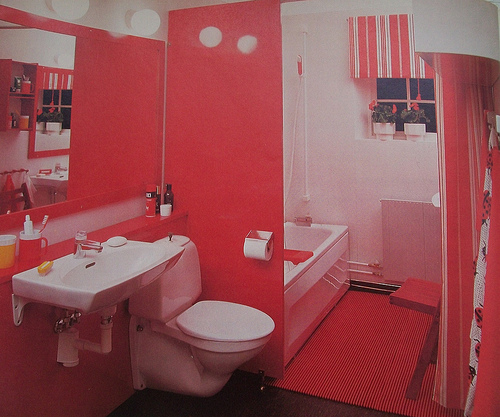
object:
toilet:
[0, 0, 500, 417]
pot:
[354, 78, 439, 144]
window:
[375, 77, 436, 133]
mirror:
[0, 18, 168, 256]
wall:
[274, 62, 370, 201]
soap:
[106, 236, 127, 247]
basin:
[62, 244, 165, 291]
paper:
[244, 230, 274, 261]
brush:
[39, 214, 50, 233]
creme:
[145, 183, 174, 218]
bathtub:
[284, 222, 351, 367]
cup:
[19, 230, 48, 266]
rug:
[389, 276, 442, 315]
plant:
[370, 94, 431, 125]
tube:
[24, 215, 34, 235]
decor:
[235, 35, 256, 55]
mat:
[269, 289, 446, 417]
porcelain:
[30, 260, 126, 313]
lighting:
[48, 0, 259, 56]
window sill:
[352, 91, 453, 168]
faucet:
[73, 230, 103, 259]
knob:
[432, 192, 440, 208]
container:
[0, 234, 18, 269]